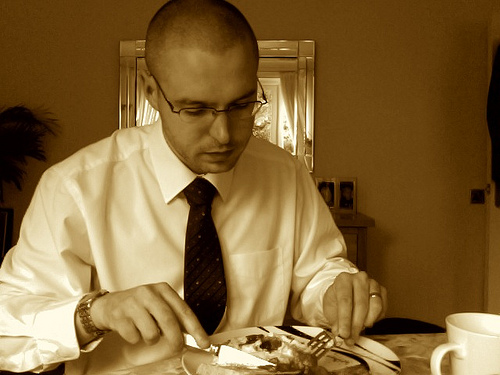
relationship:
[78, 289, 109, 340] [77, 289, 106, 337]
watch around wrist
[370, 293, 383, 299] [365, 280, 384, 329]
ring around finger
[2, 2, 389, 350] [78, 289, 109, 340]
man has watch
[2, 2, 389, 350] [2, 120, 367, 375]
man has shirt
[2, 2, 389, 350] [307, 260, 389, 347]
man has hand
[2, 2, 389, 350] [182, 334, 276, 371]
man has knife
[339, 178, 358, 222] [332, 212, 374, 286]
picture on top of cabinet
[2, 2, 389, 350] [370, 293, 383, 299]
man has ring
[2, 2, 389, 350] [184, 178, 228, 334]
man has tie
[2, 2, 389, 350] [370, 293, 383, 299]
man wearing ring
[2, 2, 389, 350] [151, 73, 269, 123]
man wearing eye glasses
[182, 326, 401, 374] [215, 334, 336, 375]
plate has food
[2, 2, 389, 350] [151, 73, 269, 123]
man has eye glasses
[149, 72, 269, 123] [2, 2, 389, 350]
eye glasses on man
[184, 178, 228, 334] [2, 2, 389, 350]
tie on man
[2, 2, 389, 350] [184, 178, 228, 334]
man wearing a tie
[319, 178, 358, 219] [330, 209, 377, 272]
picture on a cabinet